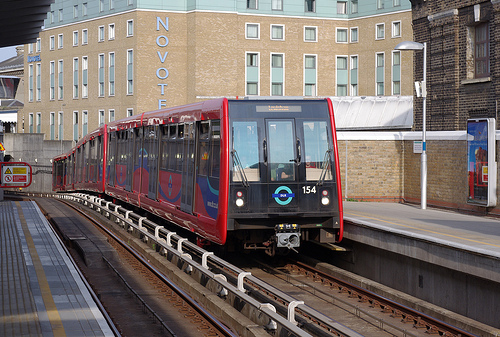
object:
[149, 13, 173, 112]
novot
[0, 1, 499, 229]
building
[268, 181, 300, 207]
emblem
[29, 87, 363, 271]
train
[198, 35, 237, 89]
brown/blue wall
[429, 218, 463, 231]
ground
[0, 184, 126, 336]
platform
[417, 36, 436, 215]
pole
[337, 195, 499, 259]
sidewalk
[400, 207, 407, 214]
ground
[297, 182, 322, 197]
154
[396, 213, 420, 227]
ground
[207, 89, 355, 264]
front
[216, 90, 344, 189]
safety glass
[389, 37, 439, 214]
light post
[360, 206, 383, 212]
ground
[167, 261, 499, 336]
track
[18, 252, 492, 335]
ground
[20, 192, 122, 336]
white line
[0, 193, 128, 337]
walk way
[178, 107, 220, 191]
window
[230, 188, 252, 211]
headlight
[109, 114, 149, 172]
window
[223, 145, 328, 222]
extinguisher